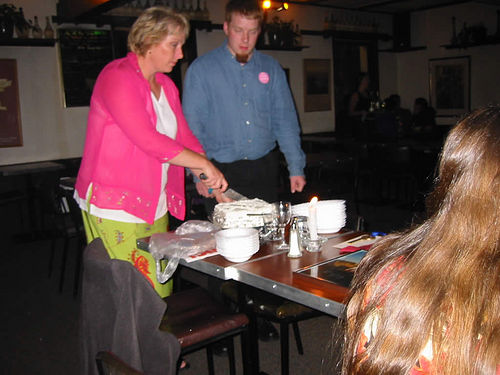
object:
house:
[0, 0, 493, 375]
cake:
[212, 198, 278, 229]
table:
[135, 231, 429, 323]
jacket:
[411, 109, 440, 131]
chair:
[80, 237, 249, 375]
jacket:
[74, 52, 206, 225]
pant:
[79, 202, 173, 301]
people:
[73, 8, 240, 370]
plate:
[294, 225, 346, 234]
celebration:
[0, 0, 500, 375]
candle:
[308, 196, 319, 251]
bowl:
[217, 250, 260, 263]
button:
[137, 197, 140, 200]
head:
[223, 0, 263, 56]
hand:
[202, 162, 229, 193]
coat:
[80, 236, 181, 375]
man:
[181, 0, 306, 223]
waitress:
[324, 108, 500, 375]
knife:
[198, 172, 250, 201]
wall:
[18, 33, 70, 161]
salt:
[287, 224, 302, 259]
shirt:
[182, 38, 307, 182]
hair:
[127, 7, 190, 59]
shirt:
[73, 86, 178, 224]